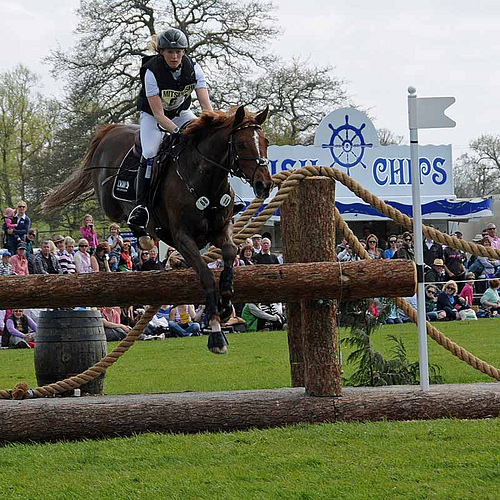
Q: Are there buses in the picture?
A: No, there are no buses.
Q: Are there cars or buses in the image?
A: No, there are no buses or cars.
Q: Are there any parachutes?
A: No, there are no parachutes.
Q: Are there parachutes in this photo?
A: No, there are no parachutes.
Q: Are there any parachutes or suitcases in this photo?
A: No, there are no parachutes or suitcases.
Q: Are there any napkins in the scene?
A: No, there are no napkins.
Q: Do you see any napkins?
A: No, there are no napkins.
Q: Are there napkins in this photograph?
A: No, there are no napkins.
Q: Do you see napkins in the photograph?
A: No, there are no napkins.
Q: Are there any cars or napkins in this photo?
A: No, there are no napkins or cars.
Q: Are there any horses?
A: Yes, there is a horse.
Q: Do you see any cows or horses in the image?
A: Yes, there is a horse.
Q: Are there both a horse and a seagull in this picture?
A: No, there is a horse but no seagulls.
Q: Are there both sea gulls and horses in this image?
A: No, there is a horse but no seagulls.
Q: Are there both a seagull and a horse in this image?
A: No, there is a horse but no seagulls.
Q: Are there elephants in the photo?
A: No, there are no elephants.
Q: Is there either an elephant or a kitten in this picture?
A: No, there are no elephants or kittens.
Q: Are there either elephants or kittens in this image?
A: No, there are no elephants or kittens.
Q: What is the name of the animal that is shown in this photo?
A: The animal is a horse.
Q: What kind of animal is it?
A: The animal is a horse.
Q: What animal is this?
A: This is a horse.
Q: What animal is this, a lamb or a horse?
A: This is a horse.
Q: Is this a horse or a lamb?
A: This is a horse.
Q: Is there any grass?
A: Yes, there is grass.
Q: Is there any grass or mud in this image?
A: Yes, there is grass.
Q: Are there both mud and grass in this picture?
A: No, there is grass but no mud.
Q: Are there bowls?
A: No, there are no bowls.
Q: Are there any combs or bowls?
A: No, there are no bowls or combs.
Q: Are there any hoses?
A: No, there are no hoses.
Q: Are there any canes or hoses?
A: No, there are no hoses or canes.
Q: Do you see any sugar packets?
A: No, there are no sugar packets.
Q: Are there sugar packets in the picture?
A: No, there are no sugar packets.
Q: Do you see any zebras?
A: No, there are no zebras.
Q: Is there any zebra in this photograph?
A: No, there are no zebras.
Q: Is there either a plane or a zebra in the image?
A: No, there are no zebras or airplanes.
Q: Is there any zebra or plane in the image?
A: No, there are no zebras or airplanes.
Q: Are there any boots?
A: Yes, there are boots.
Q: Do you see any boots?
A: Yes, there are boots.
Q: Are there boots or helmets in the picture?
A: Yes, there are boots.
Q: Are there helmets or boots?
A: Yes, there are boots.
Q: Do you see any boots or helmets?
A: Yes, there are boots.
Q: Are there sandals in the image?
A: No, there are no sandals.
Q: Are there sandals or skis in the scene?
A: No, there are no sandals or skis.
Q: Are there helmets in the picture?
A: Yes, there is a helmet.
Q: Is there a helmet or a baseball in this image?
A: Yes, there is a helmet.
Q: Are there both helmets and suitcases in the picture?
A: No, there is a helmet but no suitcases.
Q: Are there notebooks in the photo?
A: No, there are no notebooks.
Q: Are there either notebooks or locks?
A: No, there are no notebooks or locks.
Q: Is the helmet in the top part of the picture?
A: Yes, the helmet is in the top of the image.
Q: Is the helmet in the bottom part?
A: No, the helmet is in the top of the image.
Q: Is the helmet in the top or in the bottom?
A: The helmet is in the top of the image.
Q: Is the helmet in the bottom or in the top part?
A: The helmet is in the top of the image.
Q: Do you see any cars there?
A: No, there are no cars.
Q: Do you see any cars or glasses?
A: No, there are no cars or glasses.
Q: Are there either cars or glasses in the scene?
A: No, there are no cars or glasses.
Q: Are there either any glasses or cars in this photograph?
A: No, there are no cars or glasses.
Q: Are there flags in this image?
A: Yes, there is a flag.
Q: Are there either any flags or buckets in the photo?
A: Yes, there is a flag.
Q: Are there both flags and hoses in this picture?
A: No, there is a flag but no hoses.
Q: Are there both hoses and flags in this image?
A: No, there is a flag but no hoses.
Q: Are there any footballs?
A: No, there are no footballs.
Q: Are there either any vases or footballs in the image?
A: No, there are no footballs or vases.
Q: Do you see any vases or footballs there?
A: No, there are no footballs or vases.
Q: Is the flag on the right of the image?
A: Yes, the flag is on the right of the image.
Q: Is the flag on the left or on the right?
A: The flag is on the right of the image.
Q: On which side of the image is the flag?
A: The flag is on the right of the image.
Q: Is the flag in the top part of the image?
A: Yes, the flag is in the top of the image.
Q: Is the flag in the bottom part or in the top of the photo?
A: The flag is in the top of the image.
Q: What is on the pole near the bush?
A: The flag is on the pole.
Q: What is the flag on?
A: The flag is on the pole.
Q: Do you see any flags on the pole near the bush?
A: Yes, there is a flag on the pole.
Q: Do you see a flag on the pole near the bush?
A: Yes, there is a flag on the pole.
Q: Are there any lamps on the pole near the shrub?
A: No, there is a flag on the pole.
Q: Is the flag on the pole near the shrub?
A: Yes, the flag is on the pole.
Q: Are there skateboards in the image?
A: No, there are no skateboards.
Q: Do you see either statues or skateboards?
A: No, there are no skateboards or statues.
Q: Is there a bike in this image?
A: No, there are no bikes.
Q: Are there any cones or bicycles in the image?
A: No, there are no bicycles or cones.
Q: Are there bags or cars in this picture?
A: No, there are no cars or bags.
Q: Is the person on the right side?
A: No, the person is on the left of the image.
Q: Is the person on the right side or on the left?
A: The person is on the left of the image.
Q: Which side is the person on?
A: The person is on the left of the image.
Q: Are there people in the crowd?
A: Yes, there is a person in the crowd.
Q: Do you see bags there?
A: No, there are no bags.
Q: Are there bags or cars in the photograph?
A: No, there are no bags or cars.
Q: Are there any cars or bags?
A: No, there are no bags or cars.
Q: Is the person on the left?
A: Yes, the person is on the left of the image.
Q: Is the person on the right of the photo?
A: No, the person is on the left of the image.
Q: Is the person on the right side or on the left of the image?
A: The person is on the left of the image.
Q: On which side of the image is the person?
A: The person is on the left of the image.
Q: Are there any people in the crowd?
A: Yes, there is a person in the crowd.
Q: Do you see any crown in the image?
A: No, there are no crowns.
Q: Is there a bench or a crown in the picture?
A: No, there are no crowns or benches.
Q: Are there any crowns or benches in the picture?
A: No, there are no crowns or benches.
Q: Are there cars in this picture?
A: No, there are no cars.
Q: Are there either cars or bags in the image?
A: No, there are no cars or bags.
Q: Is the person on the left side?
A: Yes, the person is on the left of the image.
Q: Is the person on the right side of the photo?
A: No, the person is on the left of the image.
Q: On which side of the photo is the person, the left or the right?
A: The person is on the left of the image.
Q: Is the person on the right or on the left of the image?
A: The person is on the left of the image.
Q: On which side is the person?
A: The person is on the left of the image.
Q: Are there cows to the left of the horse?
A: No, there is a person to the left of the horse.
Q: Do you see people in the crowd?
A: Yes, there is a person in the crowd.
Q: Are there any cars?
A: No, there are no cars.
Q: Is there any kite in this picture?
A: No, there are no kites.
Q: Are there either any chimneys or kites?
A: No, there are no kites or chimneys.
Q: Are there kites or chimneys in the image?
A: No, there are no kites or chimneys.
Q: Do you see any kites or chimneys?
A: No, there are no kites or chimneys.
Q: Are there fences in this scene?
A: Yes, there is a fence.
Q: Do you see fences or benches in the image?
A: Yes, there is a fence.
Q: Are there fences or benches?
A: Yes, there is a fence.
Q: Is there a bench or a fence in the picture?
A: Yes, there is a fence.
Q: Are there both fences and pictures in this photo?
A: No, there is a fence but no pictures.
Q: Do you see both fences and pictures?
A: No, there is a fence but no pictures.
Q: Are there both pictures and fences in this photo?
A: No, there is a fence but no pictures.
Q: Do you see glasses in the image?
A: No, there are no glasses.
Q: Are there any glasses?
A: No, there are no glasses.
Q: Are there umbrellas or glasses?
A: No, there are no glasses or umbrellas.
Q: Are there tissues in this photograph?
A: No, there are no tissues.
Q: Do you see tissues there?
A: No, there are no tissues.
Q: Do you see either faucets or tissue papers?
A: No, there are no tissue papers or faucets.